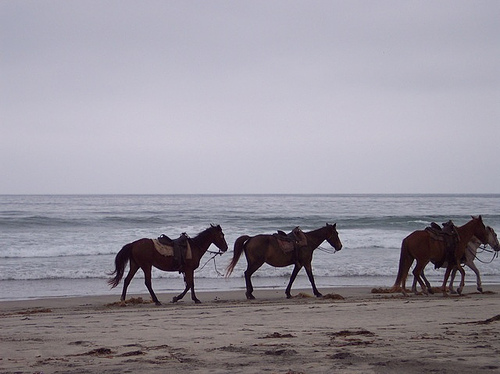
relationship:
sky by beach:
[1, 0, 499, 192] [0, 282, 499, 371]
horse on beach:
[227, 223, 342, 303] [0, 282, 499, 371]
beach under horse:
[0, 282, 499, 371] [227, 223, 342, 303]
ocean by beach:
[2, 195, 500, 279] [0, 282, 499, 371]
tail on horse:
[224, 234, 252, 276] [227, 223, 342, 303]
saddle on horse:
[270, 229, 309, 254] [227, 223, 342, 303]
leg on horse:
[303, 259, 323, 297] [227, 223, 342, 303]